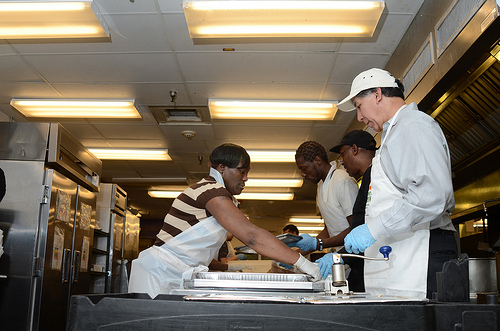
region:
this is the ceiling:
[119, 24, 177, 79]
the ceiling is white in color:
[124, 22, 170, 88]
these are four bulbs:
[8, 23, 328, 124]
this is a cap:
[336, 67, 396, 94]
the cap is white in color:
[373, 70, 388, 87]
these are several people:
[135, 67, 448, 299]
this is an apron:
[137, 257, 172, 282]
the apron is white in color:
[151, 255, 184, 282]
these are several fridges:
[15, 125, 132, 310]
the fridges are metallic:
[9, 179, 113, 252]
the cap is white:
[333, 45, 418, 123]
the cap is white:
[323, 65, 473, 195]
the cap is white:
[340, 74, 375, 111]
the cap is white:
[346, 55, 433, 155]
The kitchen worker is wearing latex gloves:
[296, 255, 314, 279]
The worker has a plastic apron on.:
[113, 220, 213, 290]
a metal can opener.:
[326, 256, 373, 283]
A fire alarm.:
[182, 130, 198, 140]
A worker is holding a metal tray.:
[231, 235, 303, 258]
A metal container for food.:
[39, 182, 110, 329]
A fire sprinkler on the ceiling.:
[166, 88, 197, 114]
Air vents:
[451, 87, 498, 158]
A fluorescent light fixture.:
[201, 93, 323, 138]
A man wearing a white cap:
[348, 65, 404, 118]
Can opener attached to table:
[328, 243, 397, 295]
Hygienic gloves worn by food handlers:
[295, 228, 377, 271]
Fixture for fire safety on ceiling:
[162, 84, 184, 104]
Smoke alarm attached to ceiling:
[172, 128, 200, 138]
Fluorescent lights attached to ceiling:
[197, 89, 343, 126]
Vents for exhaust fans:
[446, 88, 497, 157]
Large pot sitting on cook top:
[459, 252, 499, 307]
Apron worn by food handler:
[119, 198, 254, 308]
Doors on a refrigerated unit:
[15, 166, 95, 321]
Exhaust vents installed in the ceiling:
[146, 100, 216, 128]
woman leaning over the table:
[108, 135, 323, 297]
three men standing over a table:
[274, 65, 478, 298]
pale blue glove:
[338, 221, 381, 255]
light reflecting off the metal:
[52, 176, 78, 192]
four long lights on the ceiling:
[206, 95, 346, 211]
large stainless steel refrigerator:
[6, 164, 100, 329]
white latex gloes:
[290, 251, 327, 284]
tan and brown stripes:
[146, 177, 233, 242]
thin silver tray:
[234, 231, 301, 258]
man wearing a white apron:
[331, 66, 476, 304]